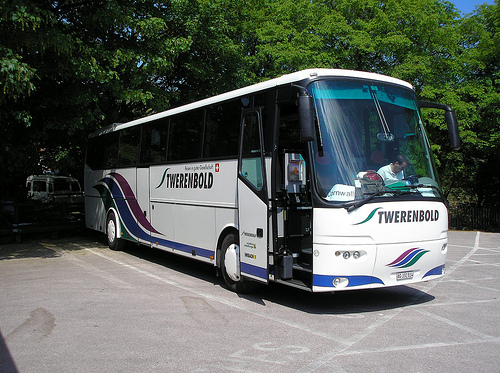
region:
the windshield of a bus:
[303, 76, 444, 207]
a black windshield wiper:
[350, 183, 405, 210]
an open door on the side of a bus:
[227, 93, 321, 293]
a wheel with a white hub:
[213, 230, 245, 285]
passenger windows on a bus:
[89, 85, 272, 172]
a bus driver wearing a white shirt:
[375, 155, 447, 221]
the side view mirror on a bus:
[418, 88, 465, 153]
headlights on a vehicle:
[322, 243, 367, 265]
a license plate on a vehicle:
[392, 267, 418, 287]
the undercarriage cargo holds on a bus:
[137, 189, 241, 263]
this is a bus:
[138, 78, 405, 278]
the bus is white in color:
[164, 197, 227, 242]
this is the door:
[268, 122, 308, 272]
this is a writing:
[163, 167, 219, 192]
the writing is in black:
[161, 172, 220, 191]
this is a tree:
[17, 9, 122, 102]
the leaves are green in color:
[32, 30, 103, 78]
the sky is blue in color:
[456, 0, 481, 18]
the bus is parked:
[130, 95, 430, 290]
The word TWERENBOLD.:
[376, 207, 438, 224]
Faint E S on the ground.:
[228, 339, 310, 366]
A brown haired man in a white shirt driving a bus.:
[375, 154, 407, 183]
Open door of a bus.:
[235, 107, 272, 284]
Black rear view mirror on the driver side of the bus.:
[415, 94, 460, 151]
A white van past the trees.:
[23, 172, 87, 202]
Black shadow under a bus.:
[91, 228, 436, 315]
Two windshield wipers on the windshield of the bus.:
[366, 84, 395, 141]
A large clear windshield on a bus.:
[309, 79, 441, 204]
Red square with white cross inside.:
[213, 162, 221, 172]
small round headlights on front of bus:
[333, 243, 449, 262]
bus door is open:
[235, 89, 327, 287]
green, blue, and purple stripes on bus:
[92, 168, 169, 245]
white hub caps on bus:
[220, 242, 249, 281]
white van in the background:
[27, 163, 83, 213]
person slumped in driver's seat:
[373, 148, 412, 185]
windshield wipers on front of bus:
[344, 176, 444, 217]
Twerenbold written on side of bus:
[163, 171, 213, 188]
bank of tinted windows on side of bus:
[85, 80, 281, 169]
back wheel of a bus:
[103, 210, 122, 250]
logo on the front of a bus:
[353, 207, 438, 224]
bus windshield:
[308, 75, 445, 205]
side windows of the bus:
[84, 93, 276, 170]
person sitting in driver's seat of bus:
[375, 154, 407, 186]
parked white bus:
[81, 68, 459, 293]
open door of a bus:
[236, 83, 314, 292]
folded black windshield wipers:
[350, 183, 441, 205]